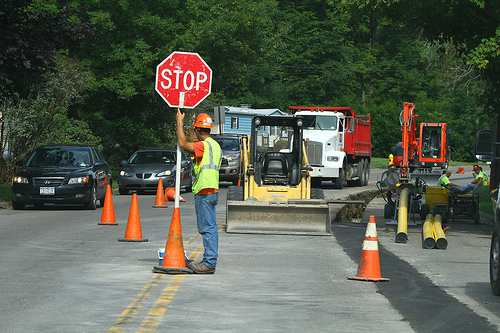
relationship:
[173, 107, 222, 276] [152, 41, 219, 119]
man holds stop sign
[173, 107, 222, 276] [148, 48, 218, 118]
man holds stop sign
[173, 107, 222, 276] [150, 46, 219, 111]
man holds stop sign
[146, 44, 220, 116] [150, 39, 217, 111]
writing on sign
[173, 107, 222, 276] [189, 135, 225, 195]
man wears safety vest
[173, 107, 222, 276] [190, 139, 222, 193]
man wears shirt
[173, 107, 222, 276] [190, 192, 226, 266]
man wears jeans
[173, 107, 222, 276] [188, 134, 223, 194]
man wearing safety vest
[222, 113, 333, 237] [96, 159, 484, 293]
bulldozer sitting at work site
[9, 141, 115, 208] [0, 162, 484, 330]
car driving on road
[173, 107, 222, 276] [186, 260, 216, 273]
man wearing boot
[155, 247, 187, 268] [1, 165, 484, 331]
water cooler sitting on ground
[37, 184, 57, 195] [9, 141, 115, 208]
license plate mounted on car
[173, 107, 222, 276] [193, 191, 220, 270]
man wearing pants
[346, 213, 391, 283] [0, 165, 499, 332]
safety cone sitting on road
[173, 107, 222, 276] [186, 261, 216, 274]
man wearing shoe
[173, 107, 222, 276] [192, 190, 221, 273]
man wearing jeans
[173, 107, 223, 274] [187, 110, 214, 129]
man wearing helmet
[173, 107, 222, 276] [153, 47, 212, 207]
man holding stop sign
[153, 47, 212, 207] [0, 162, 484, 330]
stop sign on road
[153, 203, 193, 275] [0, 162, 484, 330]
safety cone on road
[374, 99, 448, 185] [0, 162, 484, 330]
tractor on road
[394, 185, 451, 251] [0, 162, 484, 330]
pipes on road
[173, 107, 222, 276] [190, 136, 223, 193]
man wearing vest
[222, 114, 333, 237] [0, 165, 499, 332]
bulldozer on road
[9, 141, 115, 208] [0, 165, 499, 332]
car on road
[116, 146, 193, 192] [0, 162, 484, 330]
car on road